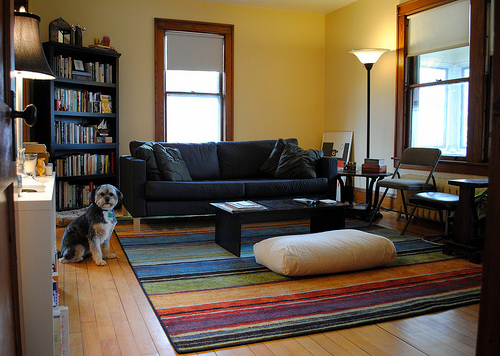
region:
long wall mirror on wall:
[144, 2, 249, 177]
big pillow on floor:
[243, 217, 410, 279]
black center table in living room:
[195, 189, 410, 256]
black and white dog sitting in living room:
[59, 183, 154, 292]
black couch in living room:
[105, 131, 374, 254]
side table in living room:
[328, 141, 406, 243]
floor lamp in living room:
[320, 31, 411, 260]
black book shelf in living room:
[37, 22, 135, 247]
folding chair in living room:
[380, 137, 462, 247]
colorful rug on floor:
[97, 201, 498, 354]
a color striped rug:
[107, 234, 467, 336]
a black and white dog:
[73, 174, 141, 268]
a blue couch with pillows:
[121, 130, 396, 235]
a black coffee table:
[218, 192, 385, 274]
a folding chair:
[383, 137, 453, 247]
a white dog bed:
[249, 226, 409, 286]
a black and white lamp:
[338, 42, 433, 190]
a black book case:
[33, 30, 131, 197]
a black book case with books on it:
[31, 18, 127, 200]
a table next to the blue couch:
[271, 129, 440, 222]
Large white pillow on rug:
[271, 219, 394, 290]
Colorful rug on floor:
[141, 225, 301, 347]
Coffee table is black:
[211, 170, 350, 260]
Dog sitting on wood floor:
[82, 167, 126, 269]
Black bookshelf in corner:
[50, 2, 112, 167]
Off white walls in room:
[256, 22, 333, 127]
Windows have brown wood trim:
[383, 26, 455, 180]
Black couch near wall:
[141, 135, 322, 190]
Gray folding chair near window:
[381, 112, 417, 242]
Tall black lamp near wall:
[344, 20, 405, 192]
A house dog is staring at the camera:
[65, 177, 127, 270]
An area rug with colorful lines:
[145, 248, 255, 326]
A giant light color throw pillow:
[263, 227, 423, 267]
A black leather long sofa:
[133, 141, 300, 191]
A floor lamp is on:
[347, 43, 384, 142]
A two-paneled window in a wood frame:
[150, 12, 260, 141]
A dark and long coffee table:
[211, 202, 363, 222]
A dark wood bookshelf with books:
[51, 45, 109, 196]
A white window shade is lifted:
[158, 29, 228, 74]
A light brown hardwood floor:
[84, 282, 125, 347]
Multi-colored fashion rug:
[112, 210, 382, 352]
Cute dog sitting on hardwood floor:
[40, 157, 189, 322]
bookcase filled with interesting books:
[22, 20, 157, 292]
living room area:
[4, 6, 474, 261]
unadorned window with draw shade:
[124, 6, 343, 206]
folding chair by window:
[365, 126, 459, 263]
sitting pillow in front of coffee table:
[195, 187, 443, 327]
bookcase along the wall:
[2, 3, 95, 354]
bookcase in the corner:
[22, 10, 154, 258]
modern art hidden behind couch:
[284, 98, 399, 252]